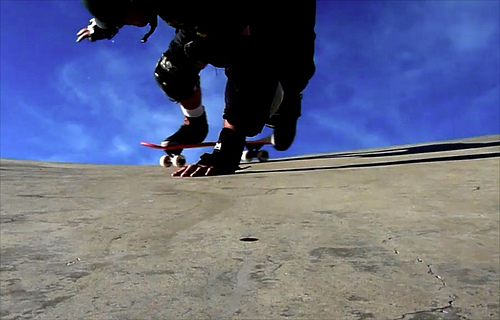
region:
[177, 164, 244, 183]
Hand on ground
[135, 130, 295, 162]
Red Skateboard on ground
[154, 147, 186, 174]
2 white wheels on front of skateboard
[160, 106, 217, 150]
Foot on skateboard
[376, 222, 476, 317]
Crack in pavement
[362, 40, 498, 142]
Blue sky in background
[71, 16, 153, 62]
Hand in air for balance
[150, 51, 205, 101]
knee pad for protection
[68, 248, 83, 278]
pebbles on ground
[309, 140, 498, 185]
Skateboarders shadow on the ground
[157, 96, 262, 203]
Hand on the pavement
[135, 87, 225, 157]
Foot on skateboard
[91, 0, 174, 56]
Chin strap is loose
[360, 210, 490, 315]
Crack in the pavement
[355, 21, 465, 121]
Blue sky with clouds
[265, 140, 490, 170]
Skateboarder's shadow on pavement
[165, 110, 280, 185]
Wearing wrist guard on wrist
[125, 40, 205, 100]
Wearing kneepad on knee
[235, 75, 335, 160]
Foot off the ground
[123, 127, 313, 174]
Skateboard with white wheels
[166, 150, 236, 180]
a hand on the pavement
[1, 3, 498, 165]
a bright blue sky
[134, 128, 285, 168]
a red skate board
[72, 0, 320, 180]
a person on a skate board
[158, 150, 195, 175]
white wheels on a skate board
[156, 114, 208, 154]
one black shoe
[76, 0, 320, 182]
a person dressed all in black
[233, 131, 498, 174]
a shadow on the pavement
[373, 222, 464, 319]
a crack in the pavement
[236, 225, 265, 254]
a spot on the pavement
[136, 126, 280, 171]
red skateboard with white wheels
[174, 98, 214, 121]
white sock on skateboarder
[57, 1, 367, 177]
skateboarder doing tricks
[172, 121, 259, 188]
left hand of skateboarder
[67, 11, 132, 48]
right hand of skateboarder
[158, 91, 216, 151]
left foot of skateboarder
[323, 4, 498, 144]
blue sky with whispy clouds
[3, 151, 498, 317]
asphalt wall with skateboarder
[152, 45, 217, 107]
right knee protector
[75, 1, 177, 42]
helmet with loose chin strap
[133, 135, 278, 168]
a red skateboard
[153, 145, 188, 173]
the front wheels of a skateboard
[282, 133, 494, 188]
the shadow of the skateboarder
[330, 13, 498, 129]
clouds in the blue sky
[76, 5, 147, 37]
the helmet of the skateboarder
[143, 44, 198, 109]
a kneepad for the skateboarder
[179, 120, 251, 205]
a hand on the ground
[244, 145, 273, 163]
the back wheels of the skateboard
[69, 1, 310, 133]
a skateboarder in black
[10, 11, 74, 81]
a lovely blue sky